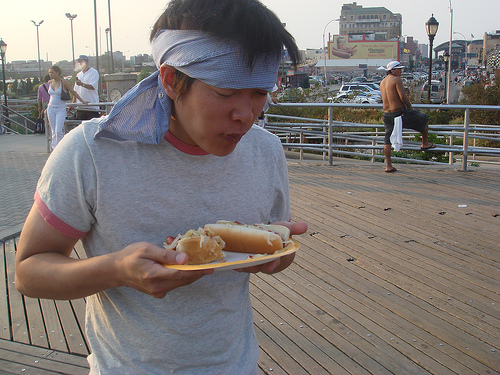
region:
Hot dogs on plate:
[158, 215, 302, 279]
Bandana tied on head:
[148, 27, 287, 94]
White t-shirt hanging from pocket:
[388, 115, 407, 153]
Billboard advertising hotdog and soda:
[323, 37, 395, 65]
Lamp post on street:
[422, 15, 438, 98]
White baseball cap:
[385, 60, 403, 70]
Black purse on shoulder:
[56, 80, 69, 101]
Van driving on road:
[416, 76, 441, 98]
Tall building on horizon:
[337, 2, 405, 39]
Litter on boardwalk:
[456, 200, 467, 210]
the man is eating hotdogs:
[24, 10, 344, 350]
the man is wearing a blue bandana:
[90, 6, 311, 151]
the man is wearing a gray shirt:
[30, 99, 325, 370]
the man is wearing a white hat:
[368, 46, 443, 182]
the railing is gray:
[305, 92, 499, 174]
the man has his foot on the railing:
[331, 55, 499, 184]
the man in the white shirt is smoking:
[44, 38, 117, 127]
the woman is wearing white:
[35, 58, 78, 153]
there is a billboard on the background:
[321, 2, 408, 79]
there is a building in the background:
[328, 0, 422, 41]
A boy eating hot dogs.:
[21, 0, 329, 366]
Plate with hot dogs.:
[155, 220, 319, 282]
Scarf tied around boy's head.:
[141, 23, 293, 97]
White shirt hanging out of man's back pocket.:
[381, 111, 415, 155]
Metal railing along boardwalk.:
[304, 96, 384, 173]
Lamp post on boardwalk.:
[422, 14, 447, 116]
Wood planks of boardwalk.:
[323, 171, 490, 370]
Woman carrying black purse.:
[45, 63, 74, 141]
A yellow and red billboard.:
[323, 32, 412, 68]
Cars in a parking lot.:
[333, 75, 378, 102]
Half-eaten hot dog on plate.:
[158, 233, 227, 262]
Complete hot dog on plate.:
[211, 216, 296, 253]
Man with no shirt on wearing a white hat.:
[377, 44, 444, 173]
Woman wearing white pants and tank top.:
[41, 62, 74, 147]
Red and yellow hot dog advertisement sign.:
[320, 31, 412, 70]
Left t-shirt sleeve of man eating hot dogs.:
[33, 118, 87, 241]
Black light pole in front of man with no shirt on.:
[420, 5, 449, 108]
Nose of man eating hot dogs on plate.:
[218, 100, 261, 126]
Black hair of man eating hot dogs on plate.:
[146, 0, 298, 39]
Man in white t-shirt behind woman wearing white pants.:
[69, 50, 106, 116]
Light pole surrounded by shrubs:
[420, 18, 440, 129]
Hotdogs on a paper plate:
[162, 225, 297, 270]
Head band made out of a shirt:
[150, 27, 286, 88]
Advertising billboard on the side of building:
[315, 18, 412, 77]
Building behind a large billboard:
[335, 1, 402, 33]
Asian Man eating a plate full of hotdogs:
[21, 15, 313, 372]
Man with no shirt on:
[368, 58, 443, 163]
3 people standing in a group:
[32, 65, 104, 150]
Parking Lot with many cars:
[291, 70, 381, 105]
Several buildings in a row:
[435, 40, 496, 66]